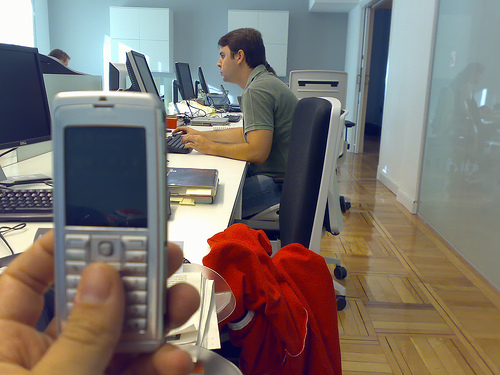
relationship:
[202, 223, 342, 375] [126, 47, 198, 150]
jacket at computer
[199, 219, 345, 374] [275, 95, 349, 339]
jacket on chair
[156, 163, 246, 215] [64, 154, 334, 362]
books on table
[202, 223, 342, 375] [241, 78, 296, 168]
jacket wearing polo shirt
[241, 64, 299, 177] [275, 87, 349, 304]
polo shirt on chair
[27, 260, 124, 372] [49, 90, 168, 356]
thumb on cellphone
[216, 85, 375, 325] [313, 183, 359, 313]
chairs with rollers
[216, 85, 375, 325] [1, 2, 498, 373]
chairs in office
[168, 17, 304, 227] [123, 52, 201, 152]
man sitting at computer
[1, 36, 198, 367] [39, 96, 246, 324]
person holding cell phone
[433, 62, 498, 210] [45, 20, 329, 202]
reflection of people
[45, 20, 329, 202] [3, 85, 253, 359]
people sitting at desks